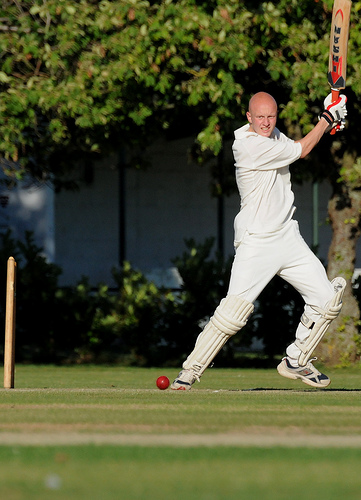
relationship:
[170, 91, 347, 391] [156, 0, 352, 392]
man playing cricket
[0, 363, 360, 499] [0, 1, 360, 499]
grass on field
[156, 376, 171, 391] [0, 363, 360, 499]
ball on grass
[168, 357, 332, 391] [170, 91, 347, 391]
shoes on man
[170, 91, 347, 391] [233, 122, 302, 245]
man wearing a shirt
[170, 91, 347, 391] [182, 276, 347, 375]
man wearing shin guards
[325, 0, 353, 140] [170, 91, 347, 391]
cricket held by man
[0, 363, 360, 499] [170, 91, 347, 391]
grass under man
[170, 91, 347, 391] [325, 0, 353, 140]
man holding cricket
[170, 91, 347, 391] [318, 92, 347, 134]
man has gloves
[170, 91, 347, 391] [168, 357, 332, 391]
man wearing shoes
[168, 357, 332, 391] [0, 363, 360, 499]
shoes on grass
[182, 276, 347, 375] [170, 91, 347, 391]
shin guards on man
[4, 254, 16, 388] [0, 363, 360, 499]
pole on grass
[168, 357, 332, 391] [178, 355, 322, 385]
shoes have laces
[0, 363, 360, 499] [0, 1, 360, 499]
grass at field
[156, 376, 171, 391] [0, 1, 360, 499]
ball at field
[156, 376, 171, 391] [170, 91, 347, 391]
ball in front of man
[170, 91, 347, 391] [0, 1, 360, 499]
man on field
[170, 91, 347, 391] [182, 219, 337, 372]
man wearing pants